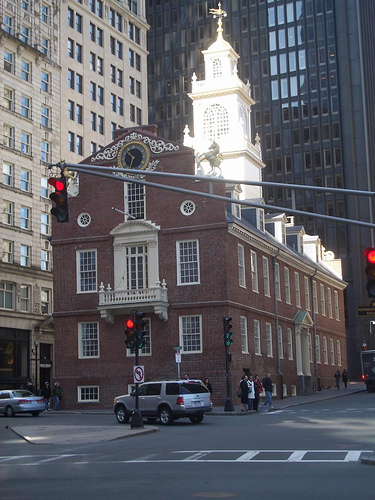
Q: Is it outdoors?
A: Yes, it is outdoors.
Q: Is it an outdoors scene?
A: Yes, it is outdoors.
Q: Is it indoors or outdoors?
A: It is outdoors.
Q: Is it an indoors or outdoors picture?
A: It is outdoors.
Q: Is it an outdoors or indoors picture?
A: It is outdoors.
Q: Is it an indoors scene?
A: No, it is outdoors.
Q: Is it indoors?
A: No, it is outdoors.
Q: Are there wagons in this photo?
A: No, there are no wagons.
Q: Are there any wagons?
A: No, there are no wagons.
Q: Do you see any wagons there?
A: No, there are no wagons.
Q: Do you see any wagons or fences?
A: No, there are no wagons or fences.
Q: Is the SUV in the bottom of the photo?
A: Yes, the SUV is in the bottom of the image.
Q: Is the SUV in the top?
A: No, the SUV is in the bottom of the image.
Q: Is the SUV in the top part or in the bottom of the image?
A: The SUV is in the bottom of the image.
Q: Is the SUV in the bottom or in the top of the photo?
A: The SUV is in the bottom of the image.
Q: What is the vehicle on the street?
A: The vehicle is a SUV.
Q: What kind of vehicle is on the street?
A: The vehicle is a SUV.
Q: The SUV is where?
A: The SUV is on the street.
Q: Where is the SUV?
A: The SUV is on the street.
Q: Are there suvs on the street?
A: Yes, there is a SUV on the street.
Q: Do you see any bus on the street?
A: No, there is a SUV on the street.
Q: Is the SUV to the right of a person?
A: No, the SUV is to the left of a person.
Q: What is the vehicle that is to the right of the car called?
A: The vehicle is a SUV.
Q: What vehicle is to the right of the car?
A: The vehicle is a SUV.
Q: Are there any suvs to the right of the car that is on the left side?
A: Yes, there is a SUV to the right of the car.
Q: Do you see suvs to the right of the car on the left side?
A: Yes, there is a SUV to the right of the car.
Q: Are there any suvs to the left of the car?
A: No, the SUV is to the right of the car.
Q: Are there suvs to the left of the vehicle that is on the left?
A: No, the SUV is to the right of the car.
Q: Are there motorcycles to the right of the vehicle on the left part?
A: No, there is a SUV to the right of the car.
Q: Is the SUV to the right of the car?
A: Yes, the SUV is to the right of the car.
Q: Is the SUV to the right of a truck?
A: No, the SUV is to the right of the car.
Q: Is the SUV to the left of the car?
A: No, the SUV is to the right of the car.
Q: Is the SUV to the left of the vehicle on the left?
A: No, the SUV is to the right of the car.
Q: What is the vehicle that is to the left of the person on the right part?
A: The vehicle is a SUV.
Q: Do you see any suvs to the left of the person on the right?
A: Yes, there is a SUV to the left of the person.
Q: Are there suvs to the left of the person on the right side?
A: Yes, there is a SUV to the left of the person.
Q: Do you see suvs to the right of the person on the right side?
A: No, the SUV is to the left of the person.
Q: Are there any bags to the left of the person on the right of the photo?
A: No, there is a SUV to the left of the person.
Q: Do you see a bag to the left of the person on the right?
A: No, there is a SUV to the left of the person.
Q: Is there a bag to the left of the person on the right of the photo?
A: No, there is a SUV to the left of the person.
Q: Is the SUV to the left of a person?
A: Yes, the SUV is to the left of a person.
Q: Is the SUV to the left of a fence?
A: No, the SUV is to the left of a person.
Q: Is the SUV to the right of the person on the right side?
A: No, the SUV is to the left of the person.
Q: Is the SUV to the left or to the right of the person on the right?
A: The SUV is to the left of the person.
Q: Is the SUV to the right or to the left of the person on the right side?
A: The SUV is to the left of the person.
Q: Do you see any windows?
A: Yes, there is a window.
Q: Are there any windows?
A: Yes, there is a window.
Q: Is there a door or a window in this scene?
A: Yes, there is a window.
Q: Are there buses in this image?
A: No, there are no buses.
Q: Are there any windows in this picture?
A: Yes, there is a window.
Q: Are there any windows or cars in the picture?
A: Yes, there is a window.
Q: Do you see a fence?
A: No, there are no fences.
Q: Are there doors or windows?
A: Yes, there is a window.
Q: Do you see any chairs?
A: No, there are no chairs.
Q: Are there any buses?
A: No, there are no buses.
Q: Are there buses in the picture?
A: No, there are no buses.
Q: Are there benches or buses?
A: No, there are no buses or benches.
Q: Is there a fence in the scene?
A: No, there are no fences.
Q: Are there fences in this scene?
A: No, there are no fences.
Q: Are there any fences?
A: No, there are no fences.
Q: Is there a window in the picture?
A: Yes, there is a window.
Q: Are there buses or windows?
A: Yes, there is a window.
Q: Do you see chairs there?
A: No, there are no chairs.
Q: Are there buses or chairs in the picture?
A: No, there are no chairs or buses.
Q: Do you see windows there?
A: Yes, there is a window.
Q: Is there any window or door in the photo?
A: Yes, there is a window.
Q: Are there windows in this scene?
A: Yes, there is a window.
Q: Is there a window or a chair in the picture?
A: Yes, there is a window.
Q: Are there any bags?
A: No, there are no bags.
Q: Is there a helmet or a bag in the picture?
A: No, there are no bags or helmets.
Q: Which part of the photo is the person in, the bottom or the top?
A: The person is in the bottom of the image.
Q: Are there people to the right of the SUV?
A: Yes, there is a person to the right of the SUV.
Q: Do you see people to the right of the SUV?
A: Yes, there is a person to the right of the SUV.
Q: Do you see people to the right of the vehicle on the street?
A: Yes, there is a person to the right of the SUV.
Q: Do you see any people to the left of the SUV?
A: No, the person is to the right of the SUV.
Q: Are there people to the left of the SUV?
A: No, the person is to the right of the SUV.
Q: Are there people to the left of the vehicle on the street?
A: No, the person is to the right of the SUV.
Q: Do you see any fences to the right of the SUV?
A: No, there is a person to the right of the SUV.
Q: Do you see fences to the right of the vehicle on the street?
A: No, there is a person to the right of the SUV.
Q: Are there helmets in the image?
A: No, there are no helmets.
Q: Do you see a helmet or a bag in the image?
A: No, there are no helmets or bags.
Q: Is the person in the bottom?
A: Yes, the person is in the bottom of the image.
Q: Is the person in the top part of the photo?
A: No, the person is in the bottom of the image.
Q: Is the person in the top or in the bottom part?
A: The person is in the bottom of the image.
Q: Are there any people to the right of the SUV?
A: Yes, there is a person to the right of the SUV.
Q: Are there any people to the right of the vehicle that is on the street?
A: Yes, there is a person to the right of the SUV.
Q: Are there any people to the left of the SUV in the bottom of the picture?
A: No, the person is to the right of the SUV.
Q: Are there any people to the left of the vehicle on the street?
A: No, the person is to the right of the SUV.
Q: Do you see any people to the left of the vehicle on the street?
A: No, the person is to the right of the SUV.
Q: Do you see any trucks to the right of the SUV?
A: No, there is a person to the right of the SUV.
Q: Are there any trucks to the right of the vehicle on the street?
A: No, there is a person to the right of the SUV.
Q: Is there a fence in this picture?
A: No, there are no fences.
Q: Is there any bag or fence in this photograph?
A: No, there are no fences or bags.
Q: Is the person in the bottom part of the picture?
A: Yes, the person is in the bottom of the image.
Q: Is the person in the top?
A: No, the person is in the bottom of the image.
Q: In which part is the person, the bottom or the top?
A: The person is in the bottom of the image.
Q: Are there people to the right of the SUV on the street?
A: Yes, there is a person to the right of the SUV.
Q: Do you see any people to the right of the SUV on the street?
A: Yes, there is a person to the right of the SUV.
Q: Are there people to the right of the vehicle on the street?
A: Yes, there is a person to the right of the SUV.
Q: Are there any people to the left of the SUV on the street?
A: No, the person is to the right of the SUV.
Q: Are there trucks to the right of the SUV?
A: No, there is a person to the right of the SUV.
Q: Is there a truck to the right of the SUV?
A: No, there is a person to the right of the SUV.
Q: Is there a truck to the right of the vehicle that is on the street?
A: No, there is a person to the right of the SUV.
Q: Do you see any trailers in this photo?
A: No, there are no trailers.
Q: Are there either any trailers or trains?
A: No, there are no trailers or trains.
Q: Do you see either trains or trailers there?
A: No, there are no trailers or trains.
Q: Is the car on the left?
A: Yes, the car is on the left of the image.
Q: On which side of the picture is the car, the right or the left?
A: The car is on the left of the image.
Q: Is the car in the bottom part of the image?
A: Yes, the car is in the bottom of the image.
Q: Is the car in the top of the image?
A: No, the car is in the bottom of the image.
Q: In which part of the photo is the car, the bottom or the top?
A: The car is in the bottom of the image.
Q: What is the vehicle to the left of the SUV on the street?
A: The vehicle is a car.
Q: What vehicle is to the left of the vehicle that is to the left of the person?
A: The vehicle is a car.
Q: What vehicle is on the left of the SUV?
A: The vehicle is a car.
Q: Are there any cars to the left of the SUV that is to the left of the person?
A: Yes, there is a car to the left of the SUV.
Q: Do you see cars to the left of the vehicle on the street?
A: Yes, there is a car to the left of the SUV.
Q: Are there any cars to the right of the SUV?
A: No, the car is to the left of the SUV.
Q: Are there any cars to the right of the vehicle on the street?
A: No, the car is to the left of the SUV.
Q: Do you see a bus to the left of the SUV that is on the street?
A: No, there is a car to the left of the SUV.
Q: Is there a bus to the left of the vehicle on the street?
A: No, there is a car to the left of the SUV.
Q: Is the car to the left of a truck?
A: No, the car is to the left of the SUV.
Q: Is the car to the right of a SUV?
A: No, the car is to the left of a SUV.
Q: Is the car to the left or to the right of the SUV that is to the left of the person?
A: The car is to the left of the SUV.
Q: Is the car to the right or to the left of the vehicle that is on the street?
A: The car is to the left of the SUV.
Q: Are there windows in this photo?
A: Yes, there is a window.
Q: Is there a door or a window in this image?
A: Yes, there is a window.